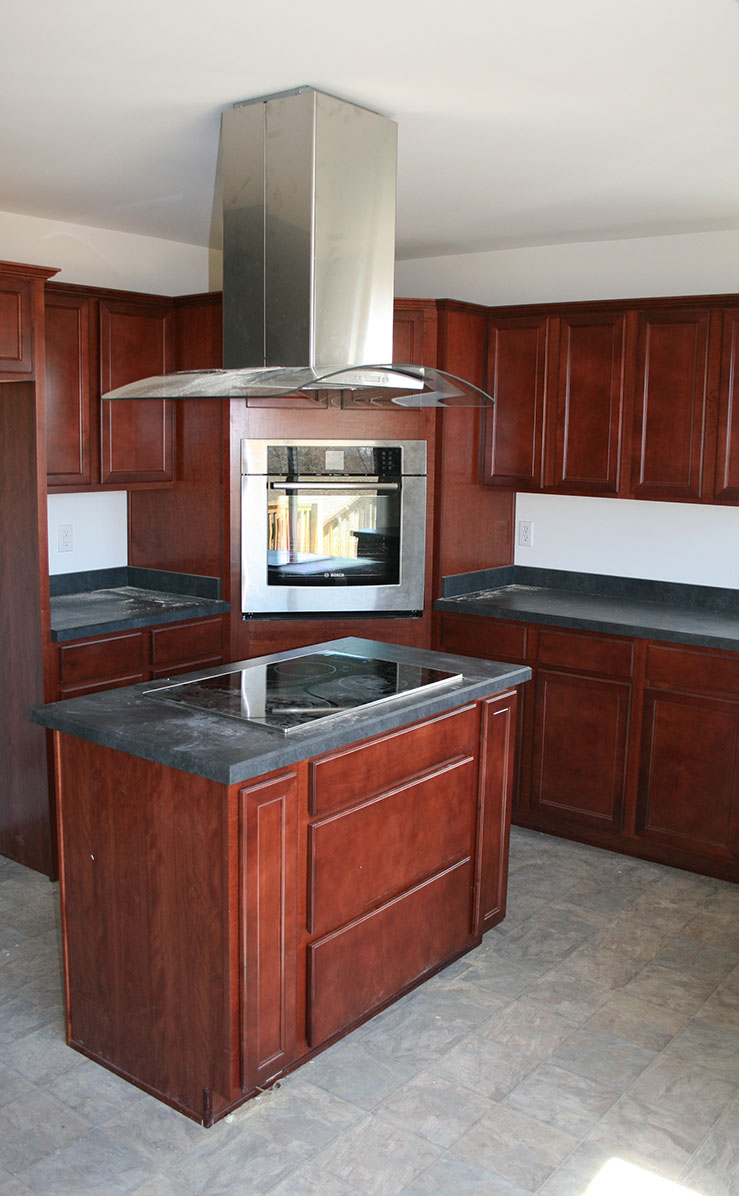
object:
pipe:
[222, 85, 398, 370]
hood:
[99, 364, 495, 406]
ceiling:
[0, 0, 738, 305]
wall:
[47, 489, 128, 574]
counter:
[49, 567, 231, 703]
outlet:
[58, 521, 74, 552]